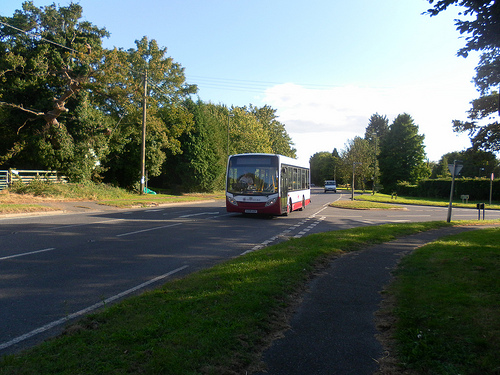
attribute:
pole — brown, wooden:
[136, 50, 163, 194]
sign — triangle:
[444, 159, 469, 181]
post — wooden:
[130, 45, 162, 198]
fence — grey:
[0, 167, 67, 192]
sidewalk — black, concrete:
[255, 219, 499, 374]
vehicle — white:
[314, 175, 341, 205]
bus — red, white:
[213, 143, 322, 225]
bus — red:
[227, 152, 313, 214]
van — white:
[322, 178, 337, 191]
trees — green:
[5, 5, 237, 189]